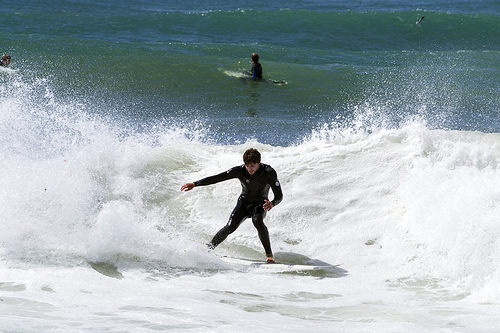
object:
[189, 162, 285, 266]
suit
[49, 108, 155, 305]
water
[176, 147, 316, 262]
person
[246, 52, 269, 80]
man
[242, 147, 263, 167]
hair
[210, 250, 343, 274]
board